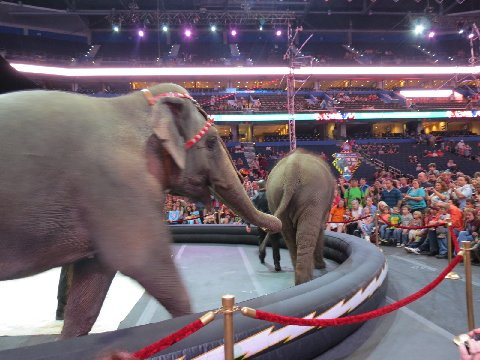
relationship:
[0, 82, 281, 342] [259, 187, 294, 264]
elephant holding tail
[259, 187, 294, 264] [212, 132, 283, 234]
tail held by trunk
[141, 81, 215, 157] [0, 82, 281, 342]
harness on elephant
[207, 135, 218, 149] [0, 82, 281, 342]
eye on elephant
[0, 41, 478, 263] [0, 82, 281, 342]
people watching elephant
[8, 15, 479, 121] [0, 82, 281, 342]
lights above elephant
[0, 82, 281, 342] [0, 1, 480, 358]
elephant in stadium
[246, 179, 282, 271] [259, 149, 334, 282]
man near elephant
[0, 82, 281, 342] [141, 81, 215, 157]
elephant wearing a harness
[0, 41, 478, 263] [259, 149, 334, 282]
people watching elephant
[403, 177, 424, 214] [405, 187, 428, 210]
woman wearing shirt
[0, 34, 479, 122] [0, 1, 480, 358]
bleachers in stadium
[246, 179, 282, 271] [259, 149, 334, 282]
man leading elephant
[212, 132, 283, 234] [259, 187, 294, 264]
trunk holding tail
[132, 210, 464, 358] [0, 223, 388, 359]
ropes around circus ring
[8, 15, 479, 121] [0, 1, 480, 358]
lights in stadium